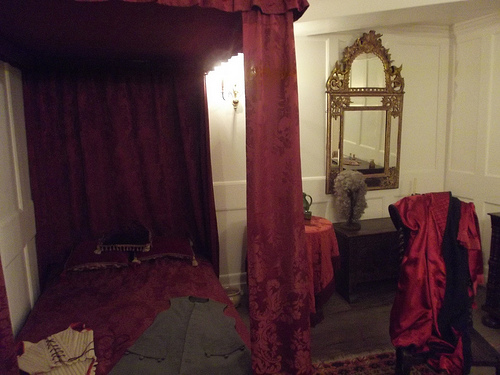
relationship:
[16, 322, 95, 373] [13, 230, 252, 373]
clothing on bed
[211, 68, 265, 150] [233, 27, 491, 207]
sconce on wall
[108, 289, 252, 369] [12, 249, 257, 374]
clothing on bed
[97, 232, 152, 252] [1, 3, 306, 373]
pillow on bed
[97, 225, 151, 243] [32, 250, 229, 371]
pillow on bed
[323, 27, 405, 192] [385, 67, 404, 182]
mirror ouline gold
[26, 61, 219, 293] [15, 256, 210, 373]
drapery behind bed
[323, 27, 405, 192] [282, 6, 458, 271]
mirror on wall